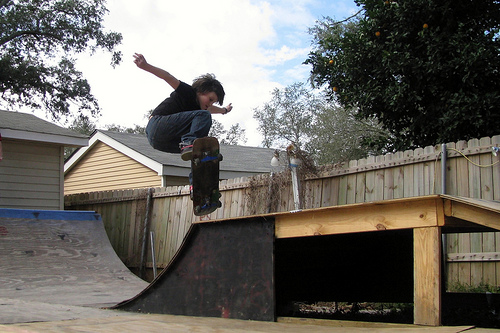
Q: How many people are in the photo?
A: One.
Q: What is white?
A: Clouds.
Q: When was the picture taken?
A: Daytime.